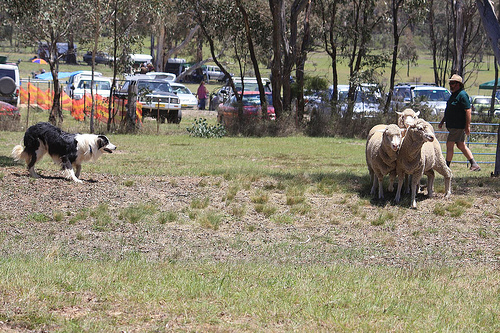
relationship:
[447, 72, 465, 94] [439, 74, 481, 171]
sunglasses on man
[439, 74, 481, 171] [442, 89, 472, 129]
man wearing green shirt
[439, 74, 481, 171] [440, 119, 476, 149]
man wearing shorts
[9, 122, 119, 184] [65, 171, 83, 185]
dog with paw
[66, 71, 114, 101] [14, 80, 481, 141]
car behind fence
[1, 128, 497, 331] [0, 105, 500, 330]
ground between grass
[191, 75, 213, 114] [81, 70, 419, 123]
person walking between cars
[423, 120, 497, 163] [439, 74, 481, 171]
fence behind man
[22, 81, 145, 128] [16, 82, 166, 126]
fabric across fence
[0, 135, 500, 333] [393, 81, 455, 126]
area behind car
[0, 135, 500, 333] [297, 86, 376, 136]
area behind car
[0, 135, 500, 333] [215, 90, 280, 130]
area behind car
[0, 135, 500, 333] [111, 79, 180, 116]
area behind car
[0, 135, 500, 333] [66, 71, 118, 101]
area behind car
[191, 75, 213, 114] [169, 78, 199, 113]
person beside car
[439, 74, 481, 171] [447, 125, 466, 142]
man wearing shorts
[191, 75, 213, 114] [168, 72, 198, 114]
person near car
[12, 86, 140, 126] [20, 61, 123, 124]
mesh on fence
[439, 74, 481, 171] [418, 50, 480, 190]
man wearing hat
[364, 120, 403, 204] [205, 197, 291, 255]
sheep standing in field